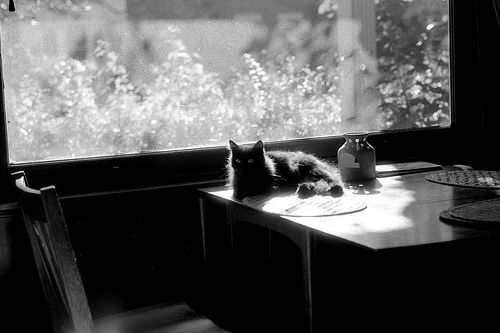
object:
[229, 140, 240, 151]
ear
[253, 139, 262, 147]
ear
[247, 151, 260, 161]
eyes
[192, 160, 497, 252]
top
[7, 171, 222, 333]
chair.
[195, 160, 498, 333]
table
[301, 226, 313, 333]
table leg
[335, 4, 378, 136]
pole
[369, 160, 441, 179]
papers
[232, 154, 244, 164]
eyes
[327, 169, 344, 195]
rear paw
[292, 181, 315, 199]
rear paw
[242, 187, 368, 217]
placemat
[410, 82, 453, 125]
ground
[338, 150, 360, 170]
label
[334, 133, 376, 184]
jar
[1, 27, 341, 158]
foliage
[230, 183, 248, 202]
legs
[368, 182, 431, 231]
ground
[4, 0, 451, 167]
window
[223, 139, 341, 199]
cat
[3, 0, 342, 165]
bush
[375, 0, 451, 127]
bush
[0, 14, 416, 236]
sun